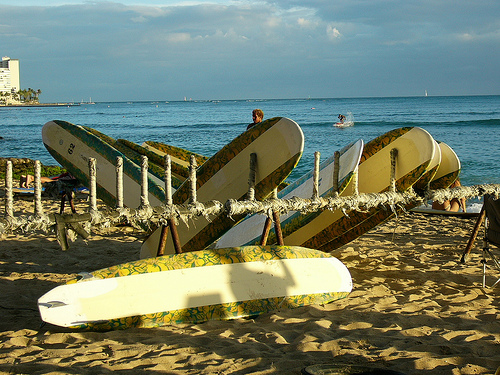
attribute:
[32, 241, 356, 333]
surf board — beige , yellow green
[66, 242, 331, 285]
design — floral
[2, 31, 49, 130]
building — tall 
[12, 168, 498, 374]
beach — sandy 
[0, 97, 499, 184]
water — blue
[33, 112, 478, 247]
surfboards — lots , leaning up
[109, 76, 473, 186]
water — blue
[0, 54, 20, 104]
building — tall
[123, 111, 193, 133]
water — blue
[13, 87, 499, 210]
blue ocean — blue 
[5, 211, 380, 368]
surfboard — end 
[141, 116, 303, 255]
surfboard — green and white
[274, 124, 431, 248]
surfboard — green and white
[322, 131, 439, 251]
surfboard — green and white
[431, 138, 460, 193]
surfboard — green and white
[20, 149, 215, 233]
surfboard rack — surfboard 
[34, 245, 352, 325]
surfboard — side , brown, white, green and white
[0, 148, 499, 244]
rack — storage 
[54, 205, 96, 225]
feet — person's two tanned